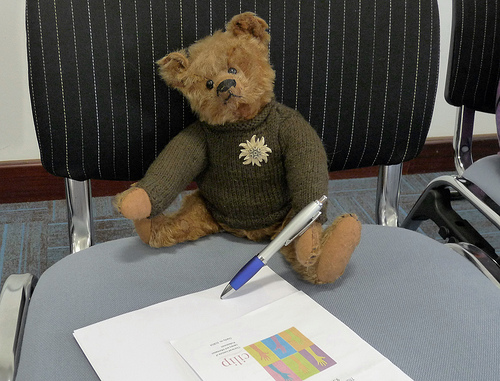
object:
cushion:
[10, 221, 500, 380]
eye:
[205, 78, 213, 90]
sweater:
[131, 100, 330, 233]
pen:
[219, 192, 328, 299]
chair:
[0, 0, 500, 381]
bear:
[109, 11, 363, 286]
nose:
[216, 78, 236, 93]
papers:
[169, 290, 416, 381]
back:
[23, 0, 441, 183]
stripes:
[24, 0, 57, 178]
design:
[237, 132, 273, 167]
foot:
[302, 213, 361, 285]